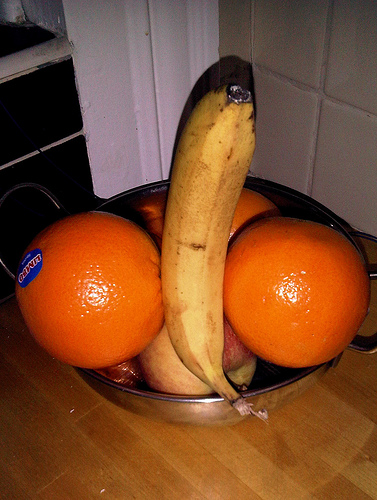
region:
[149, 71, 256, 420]
A banana in the fruit bowl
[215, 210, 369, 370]
An orange in the fruit bowl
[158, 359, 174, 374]
Part of the apple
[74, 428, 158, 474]
Part of the wood table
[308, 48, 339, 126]
Part of the wall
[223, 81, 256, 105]
A dark spot on the banana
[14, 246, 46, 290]
A red and blue sticker on the orange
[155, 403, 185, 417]
Part of the silver bowl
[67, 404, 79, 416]
A white spot on the table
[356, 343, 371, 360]
Part of the bowl handle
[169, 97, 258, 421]
banana in the middle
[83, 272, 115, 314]
reflection on the orange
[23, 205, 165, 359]
fruit is orange in color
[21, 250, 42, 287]
paper on the orange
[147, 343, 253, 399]
apple under the banana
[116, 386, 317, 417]
fruit in a silver bowl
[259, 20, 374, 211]
white tile on the wall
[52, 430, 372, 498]
bowl of fruit on wood table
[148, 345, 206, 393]
part of apple not red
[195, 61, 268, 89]
shadow on the wall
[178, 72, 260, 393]
the banana is yellow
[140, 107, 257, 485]
the banana is yellow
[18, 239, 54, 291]
a sticker on the orange's skin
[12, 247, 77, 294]
a sticker on the orange's skin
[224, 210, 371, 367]
An orange in a bowl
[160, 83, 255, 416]
A banana in a bowl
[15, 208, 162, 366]
An orange with a blue sticker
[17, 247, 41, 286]
A blue sticker on an orange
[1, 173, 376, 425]
A bowl with handles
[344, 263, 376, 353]
A handle on a bowl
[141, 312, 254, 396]
An apple in a bowl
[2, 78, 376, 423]
Fruits in a bowl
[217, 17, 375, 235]
A tiled wall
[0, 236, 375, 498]
A wooden counter surface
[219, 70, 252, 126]
dark spot on top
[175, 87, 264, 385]
banana between two oranges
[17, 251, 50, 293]
tag on orange on right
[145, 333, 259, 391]
apple under banana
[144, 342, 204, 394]
apple is green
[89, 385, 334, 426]
fruit is in silver bowl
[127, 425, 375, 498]
fruit on wooden table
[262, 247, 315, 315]
reflection on orange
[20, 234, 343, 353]
two oranges in a bowl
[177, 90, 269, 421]
banana is colored yellow